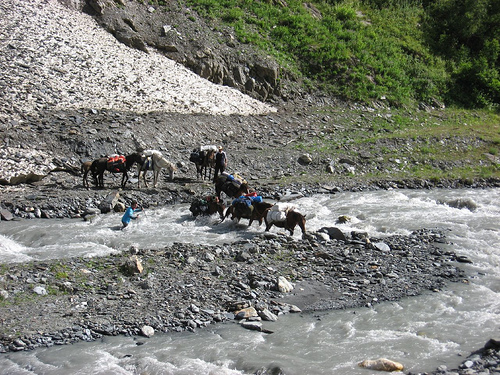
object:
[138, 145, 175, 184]
horse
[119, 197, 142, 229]
man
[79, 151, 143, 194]
horse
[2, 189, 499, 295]
river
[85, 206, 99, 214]
rock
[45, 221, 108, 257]
water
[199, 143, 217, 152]
baby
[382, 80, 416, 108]
bush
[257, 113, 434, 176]
ground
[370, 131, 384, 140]
pebble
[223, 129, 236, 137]
stone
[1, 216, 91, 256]
currents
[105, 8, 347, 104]
hill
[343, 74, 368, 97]
shrub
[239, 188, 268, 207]
top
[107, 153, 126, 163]
bag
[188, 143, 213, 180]
donkeys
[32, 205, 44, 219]
pebbles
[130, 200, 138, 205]
hat